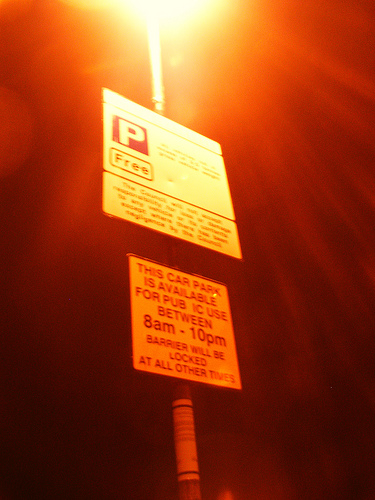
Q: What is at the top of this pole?
A: Street Light.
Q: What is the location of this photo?
A: Parking Lot entrance.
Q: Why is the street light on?
A: It is dark outside.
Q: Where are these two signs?
A: On a pole.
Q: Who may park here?
A: Public car parking.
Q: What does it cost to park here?
A: Free.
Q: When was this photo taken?
A: During the evening.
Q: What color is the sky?
A: Black.